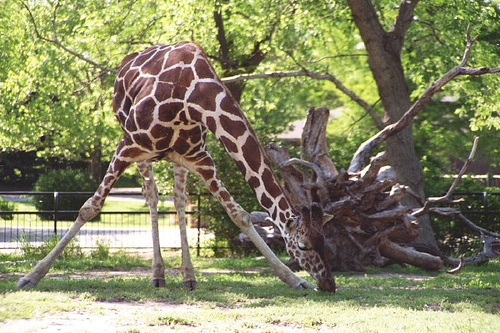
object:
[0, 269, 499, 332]
grass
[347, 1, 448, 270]
trunk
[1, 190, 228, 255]
fence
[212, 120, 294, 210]
neck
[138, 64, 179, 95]
spot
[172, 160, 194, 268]
legs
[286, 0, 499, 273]
tree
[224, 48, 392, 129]
branch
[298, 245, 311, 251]
eye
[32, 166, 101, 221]
shrub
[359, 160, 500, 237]
branches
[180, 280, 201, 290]
hooves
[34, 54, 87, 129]
leaves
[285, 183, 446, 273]
roots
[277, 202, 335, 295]
head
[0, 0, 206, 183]
trees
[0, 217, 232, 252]
road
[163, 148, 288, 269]
leg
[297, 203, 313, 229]
horns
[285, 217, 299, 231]
ear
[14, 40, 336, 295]
giraffe